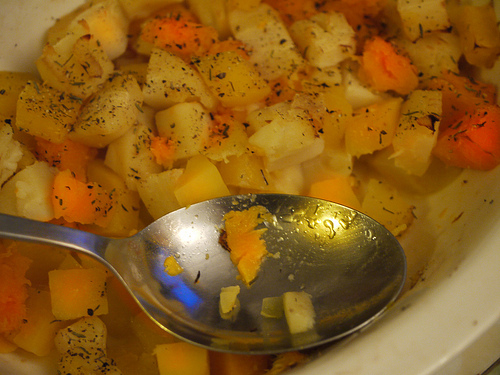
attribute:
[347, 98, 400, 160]
potatoe — brown, tan, chopped, spiced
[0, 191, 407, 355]
spoon — relective, reflective, silver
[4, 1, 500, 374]
bowl — white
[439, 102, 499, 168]
carrot — orange